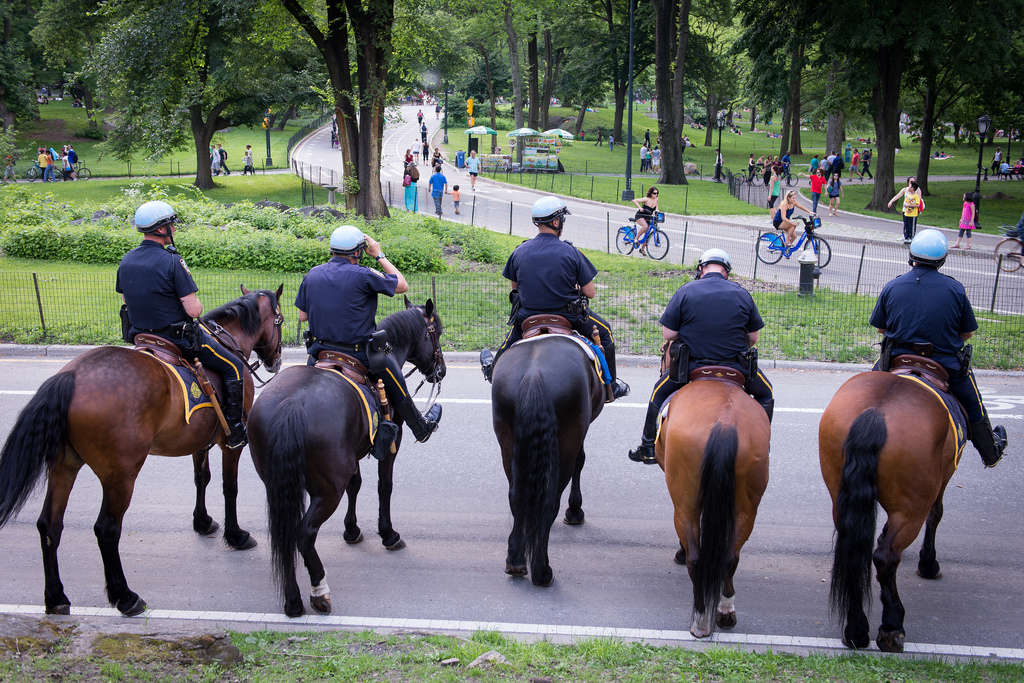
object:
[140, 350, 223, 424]
cloth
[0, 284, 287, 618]
horse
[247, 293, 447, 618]
horse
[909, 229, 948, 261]
blue helmet